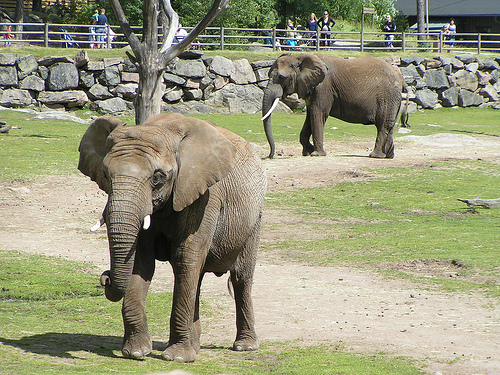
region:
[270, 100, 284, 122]
White tusk on elephant.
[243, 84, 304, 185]
Long gray trunk on elephant.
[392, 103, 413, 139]
Black hair on end of tail.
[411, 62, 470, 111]
Large gray rocks behind elephants.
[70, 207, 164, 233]
White tusks on elephant.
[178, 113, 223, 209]
Elephant has large gray ear.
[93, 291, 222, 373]
Elephant standing in the grass and dirt.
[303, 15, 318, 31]
Person wearing blue shirt.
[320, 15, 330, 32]
Person wearing black shirt.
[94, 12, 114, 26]
Person wearing blue shirt.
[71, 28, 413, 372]
two elephants in a pen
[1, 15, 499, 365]
pen of elephants are fenced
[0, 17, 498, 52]
fence of metal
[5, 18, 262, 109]
fence are over wall of rocks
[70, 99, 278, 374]
elephant has tusks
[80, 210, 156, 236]
two tasks of elephant are short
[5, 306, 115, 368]
shadow cast on green grass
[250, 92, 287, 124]
two tasks of elephant are long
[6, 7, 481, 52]
people behind fence of elephants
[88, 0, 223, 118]
a tree in a pen of elephants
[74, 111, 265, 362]
Gray elephant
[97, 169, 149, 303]
Horn of the elephant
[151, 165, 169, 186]
Left eye of the elephant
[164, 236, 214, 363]
Front left leg of the elephant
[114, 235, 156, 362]
Front right leg of the elephant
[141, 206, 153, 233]
Left tusk of the elephant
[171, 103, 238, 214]
Left ear of the elephant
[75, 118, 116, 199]
Right ear of the elephant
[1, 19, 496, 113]
Fence on top of several rocks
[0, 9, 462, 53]
Row of people watching the elephants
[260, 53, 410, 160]
An elephant in a stone enclosure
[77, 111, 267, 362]
An elephant walking in the grass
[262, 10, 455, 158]
People watching at elephant at the zoo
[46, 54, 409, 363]
Two elephants at a zoo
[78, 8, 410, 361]
People watching two elephants at the zoo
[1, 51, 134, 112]
A stone wall at the zoo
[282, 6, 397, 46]
Spectators along a fence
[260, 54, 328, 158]
Elephant head and tusks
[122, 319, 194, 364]
Feet of an elephant at the zoo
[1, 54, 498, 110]
A stone enclosure for elephants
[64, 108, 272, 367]
elephant walking and curling trunk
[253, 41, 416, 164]
elephant standing on dirt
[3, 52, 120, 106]
rock wall in background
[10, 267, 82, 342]
grass in elephant enclosure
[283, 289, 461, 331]
sand in elephant enclosure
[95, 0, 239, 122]
dead tree in background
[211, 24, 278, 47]
wood fence in background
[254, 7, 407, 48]
people watching elephants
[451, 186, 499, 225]
log on ground in elephant enclosure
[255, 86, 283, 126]
tusks on elephant